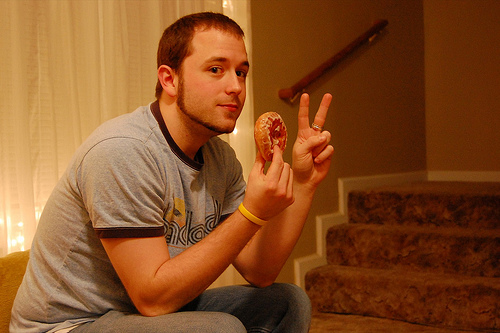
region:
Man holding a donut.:
[25, 4, 430, 324]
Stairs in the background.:
[305, 136, 448, 329]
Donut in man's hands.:
[221, 88, 321, 203]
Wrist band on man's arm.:
[232, 170, 306, 287]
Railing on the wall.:
[286, 50, 391, 130]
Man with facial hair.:
[145, 6, 280, 157]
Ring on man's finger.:
[289, 81, 337, 153]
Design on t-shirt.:
[137, 152, 239, 257]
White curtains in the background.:
[26, 10, 211, 235]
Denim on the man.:
[79, 257, 184, 326]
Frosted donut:
[243, 113, 294, 161]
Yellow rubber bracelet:
[227, 196, 271, 228]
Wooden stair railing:
[279, 13, 398, 104]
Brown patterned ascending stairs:
[300, 164, 497, 309]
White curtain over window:
[2, 5, 225, 258]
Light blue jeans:
[91, 285, 308, 332]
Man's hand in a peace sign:
[287, 74, 359, 199]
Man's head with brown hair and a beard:
[145, 10, 261, 156]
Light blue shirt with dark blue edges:
[16, 137, 248, 326]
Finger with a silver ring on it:
[305, 91, 336, 143]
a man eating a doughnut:
[2, 10, 367, 332]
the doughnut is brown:
[240, 101, 293, 168]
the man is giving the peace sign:
[268, 79, 350, 191]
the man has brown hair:
[136, 5, 273, 185]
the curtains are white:
[2, 0, 284, 259]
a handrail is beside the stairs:
[271, 14, 498, 331]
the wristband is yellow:
[224, 187, 283, 249]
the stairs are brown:
[281, 155, 498, 330]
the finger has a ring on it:
[285, 90, 330, 136]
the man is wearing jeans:
[60, 272, 318, 331]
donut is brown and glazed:
[240, 105, 289, 165]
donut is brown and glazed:
[249, 102, 306, 188]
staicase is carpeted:
[333, 250, 453, 303]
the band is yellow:
[205, 187, 282, 244]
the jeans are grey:
[231, 288, 329, 318]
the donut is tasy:
[244, 112, 297, 166]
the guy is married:
[306, 124, 328, 136]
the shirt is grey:
[56, 120, 191, 323]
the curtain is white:
[28, 78, 135, 105]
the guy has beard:
[166, 78, 246, 155]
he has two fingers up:
[289, 81, 351, 165]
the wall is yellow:
[394, 97, 489, 162]